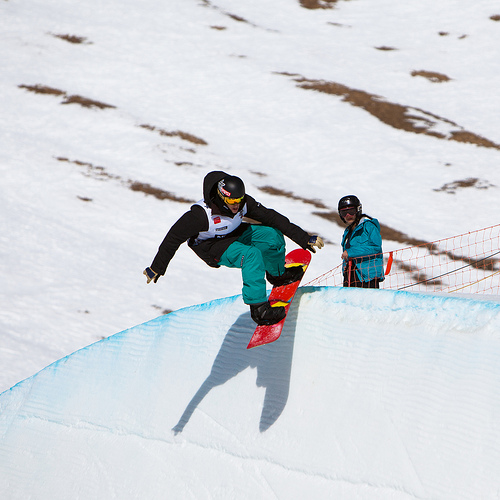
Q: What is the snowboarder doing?
A: Going down a halfpipe.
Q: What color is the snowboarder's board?
A: Red.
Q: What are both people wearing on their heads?
A: Helmets.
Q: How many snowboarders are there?
A: Two.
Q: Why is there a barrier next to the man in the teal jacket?
A: To ensure people's safety.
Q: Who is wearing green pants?
A: The snowboarder with the red board.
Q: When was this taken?
A: During the day.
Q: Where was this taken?
A: At a snowboarding halfpipe.